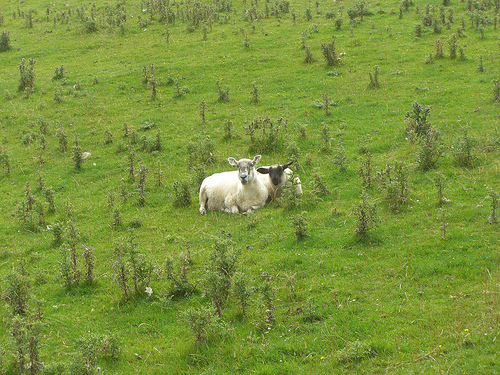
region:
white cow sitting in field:
[186, 141, 264, 225]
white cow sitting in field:
[261, 151, 295, 209]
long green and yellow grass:
[26, 234, 63, 259]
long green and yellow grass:
[120, 259, 168, 300]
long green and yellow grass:
[250, 264, 281, 282]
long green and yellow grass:
[326, 203, 386, 254]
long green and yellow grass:
[351, 286, 412, 316]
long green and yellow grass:
[353, 26, 391, 87]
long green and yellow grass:
[89, 109, 133, 127]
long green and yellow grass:
[140, 76, 185, 113]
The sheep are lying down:
[193, 152, 295, 212]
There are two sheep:
[193, 147, 302, 212]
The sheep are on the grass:
[186, 144, 308, 224]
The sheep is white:
[196, 149, 265, 214]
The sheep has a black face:
[258, 154, 303, 194]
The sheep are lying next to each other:
[201, 147, 303, 219]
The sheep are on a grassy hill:
[10, 27, 488, 362]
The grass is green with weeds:
[7, 29, 489, 363]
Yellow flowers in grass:
[431, 322, 478, 361]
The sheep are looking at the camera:
[196, 154, 298, 214]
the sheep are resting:
[151, 118, 353, 232]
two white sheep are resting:
[186, 128, 333, 254]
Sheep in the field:
[198, 155, 289, 212]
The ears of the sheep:
[227, 155, 262, 167]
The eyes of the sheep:
[233, 162, 256, 168]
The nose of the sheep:
[238, 171, 248, 177]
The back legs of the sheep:
[198, 188, 208, 213]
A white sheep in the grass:
[196, 156, 267, 213]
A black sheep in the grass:
[256, 165, 301, 192]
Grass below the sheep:
[1, 0, 496, 374]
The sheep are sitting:
[200, 154, 300, 210]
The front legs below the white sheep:
[229, 203, 256, 215]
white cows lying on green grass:
[195, 148, 305, 216]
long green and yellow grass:
[25, 24, 79, 64]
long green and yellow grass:
[343, 190, 400, 227]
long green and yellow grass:
[372, 119, 416, 167]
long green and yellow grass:
[272, 89, 333, 124]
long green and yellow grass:
[167, 112, 198, 147]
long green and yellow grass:
[108, 178, 136, 231]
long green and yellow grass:
[142, 289, 209, 326]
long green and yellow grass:
[197, 280, 272, 354]